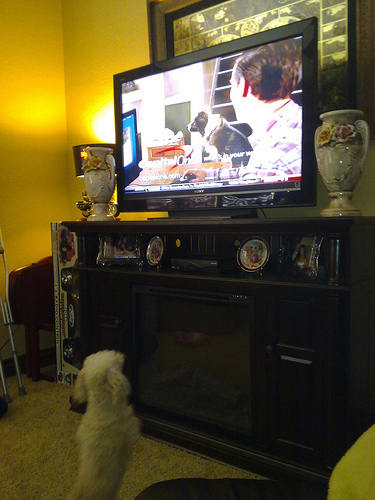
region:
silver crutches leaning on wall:
[0, 214, 30, 413]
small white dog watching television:
[47, 339, 171, 497]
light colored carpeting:
[11, 419, 66, 490]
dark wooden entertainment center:
[48, 219, 371, 484]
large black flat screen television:
[99, 17, 348, 222]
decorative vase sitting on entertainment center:
[315, 104, 373, 217]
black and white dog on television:
[170, 98, 258, 170]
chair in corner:
[5, 238, 68, 386]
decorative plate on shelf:
[234, 237, 270, 282]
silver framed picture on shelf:
[92, 233, 143, 271]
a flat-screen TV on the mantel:
[75, 17, 345, 225]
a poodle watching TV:
[23, 320, 165, 498]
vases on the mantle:
[63, 109, 367, 207]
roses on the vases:
[305, 122, 368, 155]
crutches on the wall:
[0, 214, 19, 433]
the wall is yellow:
[10, 6, 157, 238]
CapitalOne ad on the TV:
[119, 137, 287, 197]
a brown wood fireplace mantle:
[57, 215, 357, 485]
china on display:
[136, 232, 285, 273]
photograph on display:
[276, 224, 341, 280]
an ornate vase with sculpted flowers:
[77, 141, 116, 221]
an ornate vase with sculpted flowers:
[314, 108, 368, 219]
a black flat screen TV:
[94, 18, 316, 216]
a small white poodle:
[66, 346, 145, 496]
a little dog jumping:
[64, 346, 145, 497]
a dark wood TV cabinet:
[68, 208, 366, 479]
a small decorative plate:
[231, 233, 266, 275]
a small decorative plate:
[143, 231, 164, 266]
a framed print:
[141, 1, 371, 157]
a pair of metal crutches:
[0, 231, 30, 407]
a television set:
[110, 15, 318, 222]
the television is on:
[109, 14, 322, 214]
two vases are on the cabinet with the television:
[73, 108, 374, 219]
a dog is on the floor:
[62, 340, 140, 498]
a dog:
[64, 347, 139, 498]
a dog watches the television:
[63, 342, 147, 498]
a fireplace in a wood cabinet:
[116, 282, 267, 444]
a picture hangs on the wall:
[144, 0, 363, 136]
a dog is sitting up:
[60, 341, 140, 498]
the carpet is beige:
[1, 368, 277, 498]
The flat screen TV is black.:
[94, 13, 320, 209]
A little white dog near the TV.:
[35, 343, 153, 497]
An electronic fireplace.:
[107, 278, 269, 441]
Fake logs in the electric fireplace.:
[135, 333, 240, 409]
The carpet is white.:
[11, 426, 68, 473]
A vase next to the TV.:
[311, 94, 371, 212]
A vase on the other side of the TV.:
[67, 136, 115, 212]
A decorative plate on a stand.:
[230, 230, 269, 275]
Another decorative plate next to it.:
[126, 232, 167, 267]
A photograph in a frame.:
[79, 227, 153, 268]